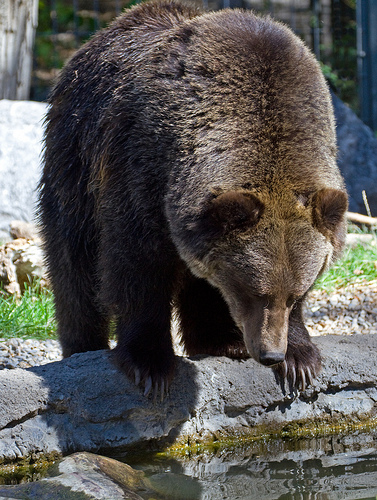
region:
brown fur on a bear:
[167, 36, 271, 129]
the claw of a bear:
[128, 360, 184, 405]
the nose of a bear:
[247, 342, 300, 368]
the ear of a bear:
[212, 190, 253, 228]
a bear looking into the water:
[58, 145, 362, 467]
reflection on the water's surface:
[261, 456, 326, 491]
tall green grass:
[8, 293, 55, 340]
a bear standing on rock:
[97, 347, 328, 411]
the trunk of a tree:
[1, 18, 40, 68]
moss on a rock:
[178, 423, 282, 447]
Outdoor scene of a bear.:
[34, 9, 328, 456]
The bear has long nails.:
[118, 353, 354, 414]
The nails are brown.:
[110, 337, 330, 407]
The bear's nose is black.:
[241, 351, 286, 374]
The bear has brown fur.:
[79, 144, 164, 225]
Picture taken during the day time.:
[13, 159, 71, 360]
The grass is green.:
[0, 281, 43, 334]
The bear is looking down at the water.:
[214, 207, 326, 404]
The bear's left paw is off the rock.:
[265, 295, 337, 411]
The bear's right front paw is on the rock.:
[71, 245, 164, 438]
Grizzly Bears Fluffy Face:
[171, 156, 330, 366]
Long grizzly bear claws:
[105, 324, 191, 411]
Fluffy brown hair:
[61, 59, 148, 185]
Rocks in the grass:
[334, 285, 374, 344]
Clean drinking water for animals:
[254, 451, 334, 493]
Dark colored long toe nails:
[97, 322, 189, 413]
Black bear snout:
[244, 340, 302, 384]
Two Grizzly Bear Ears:
[200, 160, 355, 247]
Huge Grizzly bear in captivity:
[64, 7, 326, 386]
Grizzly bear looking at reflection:
[119, 203, 358, 498]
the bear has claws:
[133, 353, 321, 407]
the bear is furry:
[37, 0, 354, 417]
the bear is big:
[30, 1, 360, 405]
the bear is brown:
[35, 1, 343, 407]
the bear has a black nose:
[256, 348, 293, 374]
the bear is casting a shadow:
[23, 343, 212, 498]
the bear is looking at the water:
[23, 2, 352, 415]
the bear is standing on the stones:
[0, 324, 376, 471]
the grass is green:
[0, 211, 375, 356]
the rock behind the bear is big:
[0, 66, 374, 281]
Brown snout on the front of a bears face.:
[245, 299, 290, 367]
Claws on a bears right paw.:
[130, 364, 171, 401]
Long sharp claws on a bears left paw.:
[280, 359, 322, 389]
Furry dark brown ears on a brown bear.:
[202, 185, 347, 232]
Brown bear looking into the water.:
[35, 0, 348, 403]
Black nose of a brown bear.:
[259, 349, 286, 366]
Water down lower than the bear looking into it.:
[130, 433, 375, 499]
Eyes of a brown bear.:
[249, 290, 303, 304]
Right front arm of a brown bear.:
[97, 177, 177, 401]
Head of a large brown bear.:
[165, 172, 347, 368]